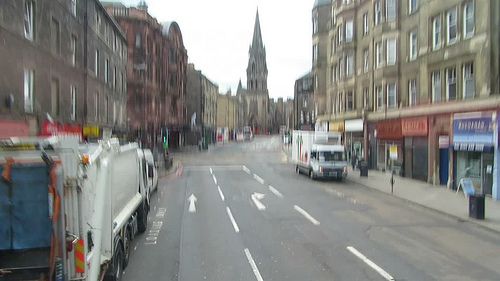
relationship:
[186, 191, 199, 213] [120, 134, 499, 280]
arrow on road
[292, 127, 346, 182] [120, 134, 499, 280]
van on road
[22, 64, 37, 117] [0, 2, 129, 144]
window on building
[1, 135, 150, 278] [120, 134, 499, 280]
truck on road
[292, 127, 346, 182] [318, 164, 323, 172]
van has headlight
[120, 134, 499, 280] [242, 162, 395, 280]
road has broken lines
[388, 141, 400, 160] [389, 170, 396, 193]
sign on pole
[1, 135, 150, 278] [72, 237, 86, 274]
truck has spiral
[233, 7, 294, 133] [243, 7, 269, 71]
building has point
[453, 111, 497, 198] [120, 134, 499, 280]
storefront along road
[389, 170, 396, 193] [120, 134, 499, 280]
parking meter near road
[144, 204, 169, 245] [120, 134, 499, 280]
word on road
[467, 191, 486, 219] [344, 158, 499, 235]
trash bin on sidewalk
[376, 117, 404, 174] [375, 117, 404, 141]
store has sign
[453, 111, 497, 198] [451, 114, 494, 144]
storefront has sign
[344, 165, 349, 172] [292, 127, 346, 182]
headlight on van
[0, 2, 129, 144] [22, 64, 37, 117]
building has window